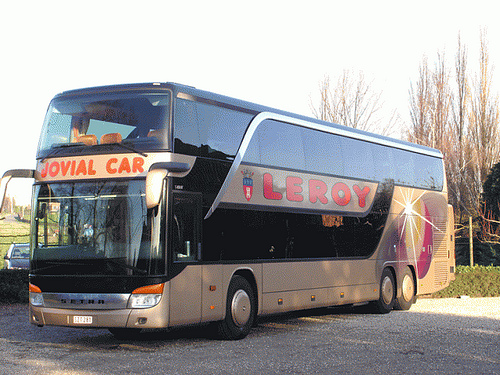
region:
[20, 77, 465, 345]
A black and brown bus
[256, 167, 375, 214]
The word "LEROY" in red letters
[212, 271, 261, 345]
A black round tire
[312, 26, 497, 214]
Two trees in the background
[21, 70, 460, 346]
Bus is double decker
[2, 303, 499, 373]
Shadows on the ground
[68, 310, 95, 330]
A white license plate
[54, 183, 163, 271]
Reflections on the window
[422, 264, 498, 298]
A patch of green grass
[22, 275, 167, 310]
Two headlights on a bus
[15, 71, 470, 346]
A bus in the foreground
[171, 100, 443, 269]
Busses side windows are tinted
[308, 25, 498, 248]
A tall tree in the background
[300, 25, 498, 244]
Tree in the background is bare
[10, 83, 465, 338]
The bus is a double decker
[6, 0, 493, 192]
The sky is white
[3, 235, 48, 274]
A car in the background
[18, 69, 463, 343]
The bus is parked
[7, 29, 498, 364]
Photo was taken outdoors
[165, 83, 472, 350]
A side view of a bus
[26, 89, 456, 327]
Bus parked on gravel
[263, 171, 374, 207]
Word "LEROY" on side of bus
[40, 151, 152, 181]
"JOVIAL CAR" on front of bus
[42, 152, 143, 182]
Gold background with orange lettering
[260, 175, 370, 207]
Gold background with red lettering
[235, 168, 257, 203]
Red, blue, and white design on bus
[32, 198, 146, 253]
Windshield of large bus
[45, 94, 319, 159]
Top cabin of bus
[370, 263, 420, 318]
Tires of bus on gravel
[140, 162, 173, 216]
Gold side mirror of bus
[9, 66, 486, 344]
bus parked in a lot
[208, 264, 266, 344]
front wheel on a bus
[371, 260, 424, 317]
rear wheels on a bus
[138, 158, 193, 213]
side rear view mirror on a bus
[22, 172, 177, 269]
front windshield on a bus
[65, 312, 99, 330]
front licence plate on a bus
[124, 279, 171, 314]
front headlight on a bus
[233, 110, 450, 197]
side windows on a bus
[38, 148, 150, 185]
lettering on the front of a bus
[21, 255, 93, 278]
windshield washer on a bus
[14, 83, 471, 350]
A double decker bus.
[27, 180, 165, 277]
Bottom windshield on bus.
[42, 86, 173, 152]
Top front window on bus.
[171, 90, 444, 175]
Passenger windows on the top.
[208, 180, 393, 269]
Passenger windows on the bottom.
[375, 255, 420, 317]
Two back rear tires.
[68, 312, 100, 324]
White tag on bumper.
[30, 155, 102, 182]
The word JOVIAL on front of bus.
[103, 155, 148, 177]
The word CAR on front of bus.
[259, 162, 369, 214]
The word LEROY on side of bus.